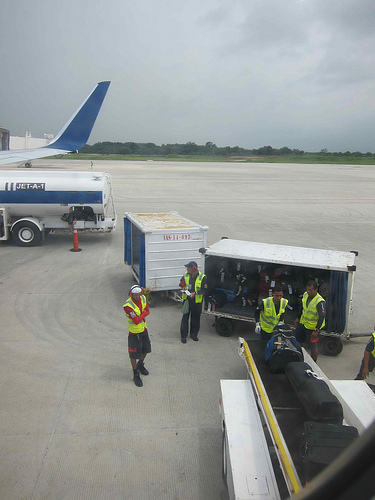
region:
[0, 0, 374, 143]
Sky covered with mist and rain clouds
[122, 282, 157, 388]
Man wearing a reflective clothing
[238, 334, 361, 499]
Baggage conveyor with bags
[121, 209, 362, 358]
White airport baggage trail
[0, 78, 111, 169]
Wing tip of an airliner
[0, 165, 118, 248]
Back end of a fuel tanker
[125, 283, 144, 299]
Ear muffs worn over a white cap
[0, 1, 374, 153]
Sky ladden with mist and rain clouds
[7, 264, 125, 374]
Tire marks on the smooth concrete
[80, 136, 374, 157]
Thick, lush, green bushes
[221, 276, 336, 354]
People loading luggage on the plane.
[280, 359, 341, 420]
A long black luggage on the loading bin.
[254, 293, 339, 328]
The men is wearing a yellow vest.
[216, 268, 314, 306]
The cart is full of luggage.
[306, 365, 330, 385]
The luggage has a white tag.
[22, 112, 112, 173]
A plane sitting on the terminal.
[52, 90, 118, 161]
The tail of the plane is blue.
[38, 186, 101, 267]
A orange cone by the tank.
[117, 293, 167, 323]
The man is folding his arms.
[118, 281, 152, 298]
The man is wearing headphone.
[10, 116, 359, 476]
airport employees and service vehicles on ground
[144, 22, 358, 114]
gray sky with dark clouds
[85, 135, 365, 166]
row of trees and grasses in distance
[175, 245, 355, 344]
workers in front of luggage cart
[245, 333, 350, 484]
conveyor belt with dark suitcases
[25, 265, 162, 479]
employee wearing helmet with arms folded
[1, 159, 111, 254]
blue and white tanker behind orange cone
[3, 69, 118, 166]
blue and white tail curving upward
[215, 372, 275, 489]
tire and side panel of truck with luggage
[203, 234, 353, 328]
cart filled with tagged luggage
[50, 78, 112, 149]
blue tip of a plane wing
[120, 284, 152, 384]
man in safety vest standing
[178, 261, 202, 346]
man in safety vest standing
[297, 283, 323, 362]
man in safety vest standing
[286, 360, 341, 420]
luggage on a conveyer belt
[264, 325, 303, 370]
luggage on a conveyer belt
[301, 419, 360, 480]
luggage on a conveyer belt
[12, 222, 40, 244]
wheel of a tanker truck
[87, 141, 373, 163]
line of trees in the distance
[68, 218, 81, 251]
an orange and white cone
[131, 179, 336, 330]
Vehicles on the pavement.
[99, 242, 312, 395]
Men on the pavement.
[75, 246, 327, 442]
Men in yellow vests.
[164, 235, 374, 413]
Men unloading the vehicle.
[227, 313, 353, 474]
Luggage being unloaded.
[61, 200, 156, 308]
Cone on the pavement.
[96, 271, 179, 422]
Man with a red shirt.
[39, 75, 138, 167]
Blue tail on the plane.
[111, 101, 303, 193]
Trees in the background.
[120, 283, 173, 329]
man with white hat.